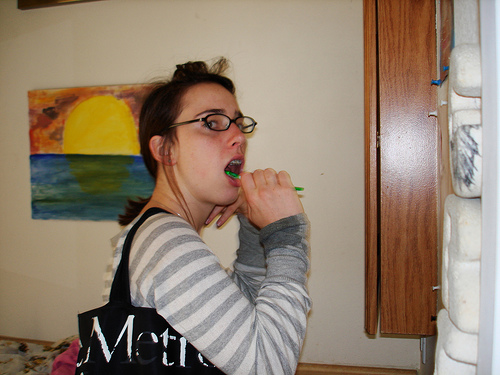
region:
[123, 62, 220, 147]
girl's hair is tied back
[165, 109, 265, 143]
girl is wearing eye glasses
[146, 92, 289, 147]
eye glasses with black rims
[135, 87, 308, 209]
girl brushing teeth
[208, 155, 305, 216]
tooth brush is in the right hand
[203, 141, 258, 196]
girl has braces on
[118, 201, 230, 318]
girl is wearing a striped shirt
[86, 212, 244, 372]
black bag over shoulder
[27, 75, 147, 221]
painting of sunset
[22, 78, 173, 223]
picture hung up on wall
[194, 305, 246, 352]
gray stripe on shirt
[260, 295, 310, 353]
gray stripe on shirt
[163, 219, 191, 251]
gray stripe on shirt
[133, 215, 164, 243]
gray stripe on shirt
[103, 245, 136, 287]
gray stripe on shirt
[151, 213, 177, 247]
gray stripe on shirt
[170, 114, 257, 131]
The girl is wearing eyeglasses.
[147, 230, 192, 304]
The shirt is striped.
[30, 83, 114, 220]
A painting is on the wall.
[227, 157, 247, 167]
The girl has braces.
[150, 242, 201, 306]
The shirt is grey and white.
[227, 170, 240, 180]
The toothbrush is green.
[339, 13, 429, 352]
an oak cabinet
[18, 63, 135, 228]
a painting of a sunset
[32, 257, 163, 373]
a black tote bag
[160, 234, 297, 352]
a grey and white striped sweater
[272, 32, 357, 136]
a white wall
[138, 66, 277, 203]
a girl wearing glasses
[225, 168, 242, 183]
a green toothbrush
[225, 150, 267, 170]
teeth with braces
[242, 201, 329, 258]
a wet sweater sleeve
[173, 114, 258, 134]
a pair of black frame glasses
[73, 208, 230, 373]
a black and white shoulder bag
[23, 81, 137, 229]
a painting on a wall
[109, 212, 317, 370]
a gray and white shirt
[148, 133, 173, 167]
a right ear of a lady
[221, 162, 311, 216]
a hand holding a green tooth brush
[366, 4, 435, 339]
a brown wall cabinet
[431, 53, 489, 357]
white letters on a wall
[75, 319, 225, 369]
white letters on a shoulder bag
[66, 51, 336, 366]
a person brushing her teeth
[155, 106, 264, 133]
a woman's black eyeglass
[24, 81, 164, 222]
a colorful hanging wall picture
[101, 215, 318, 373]
a woman's long sleeve striped shirt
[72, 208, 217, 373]
a black and white bag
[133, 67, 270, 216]
head of the girl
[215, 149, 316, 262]
hand of the girl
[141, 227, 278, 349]
stripes on the shirt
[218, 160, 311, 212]
green item in girl's mouth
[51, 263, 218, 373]
words on the bag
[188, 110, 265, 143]
glasses on the girl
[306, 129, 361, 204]
wall near the girl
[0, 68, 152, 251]
painting near the girl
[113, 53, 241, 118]
brown hair on girl